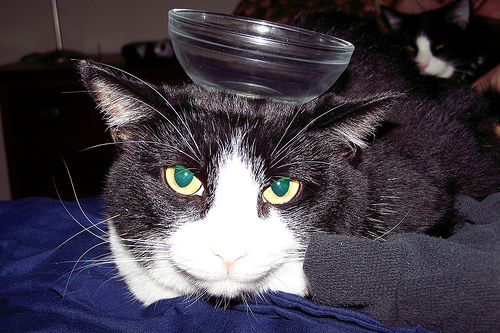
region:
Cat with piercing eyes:
[73, 60, 486, 324]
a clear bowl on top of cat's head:
[162, 8, 365, 116]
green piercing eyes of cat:
[160, 135, 312, 222]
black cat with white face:
[77, 45, 472, 312]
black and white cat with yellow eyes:
[387, 15, 492, 105]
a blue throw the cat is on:
[13, 190, 325, 331]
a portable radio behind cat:
[119, 32, 184, 83]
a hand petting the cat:
[474, 60, 499, 137]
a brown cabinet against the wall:
[13, 41, 132, 218]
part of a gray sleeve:
[314, 221, 498, 331]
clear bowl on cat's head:
[166, 8, 359, 99]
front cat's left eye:
[272, 173, 304, 207]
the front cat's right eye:
[162, 165, 207, 193]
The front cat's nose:
[207, 230, 259, 265]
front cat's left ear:
[314, 92, 409, 159]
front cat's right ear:
[83, 63, 173, 132]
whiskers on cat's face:
[50, 158, 110, 284]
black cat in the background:
[380, 3, 497, 75]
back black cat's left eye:
[432, 40, 450, 57]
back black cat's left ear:
[453, 3, 477, 33]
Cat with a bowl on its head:
[163, 20, 302, 93]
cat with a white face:
[155, 195, 287, 287]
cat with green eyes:
[154, 152, 304, 202]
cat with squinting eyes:
[386, 20, 475, 88]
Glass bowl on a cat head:
[158, 4, 327, 106]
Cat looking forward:
[52, 50, 377, 262]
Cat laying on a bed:
[111, 44, 371, 256]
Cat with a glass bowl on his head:
[132, 33, 321, 188]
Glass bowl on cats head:
[178, 32, 300, 117]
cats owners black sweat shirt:
[303, 190, 498, 331]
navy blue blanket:
[1, 184, 433, 331]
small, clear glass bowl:
[166, 7, 354, 103]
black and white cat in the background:
[378, 0, 499, 81]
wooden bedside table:
[1, 49, 193, 198]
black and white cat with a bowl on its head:
[51, 10, 491, 307]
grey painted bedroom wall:
[2, 0, 239, 202]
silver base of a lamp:
[38, 0, 93, 64]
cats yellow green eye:
[256, 173, 304, 209]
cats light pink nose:
[208, 244, 246, 274]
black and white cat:
[77, 50, 474, 307]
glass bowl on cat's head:
[160, 7, 350, 97]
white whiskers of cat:
[55, 155, 401, 283]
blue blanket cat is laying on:
[15, 197, 382, 330]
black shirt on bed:
[303, 212, 498, 329]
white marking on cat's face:
[153, 144, 298, 299]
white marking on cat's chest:
[104, 231, 311, 314]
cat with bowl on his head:
[66, 14, 498, 286]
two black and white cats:
[55, 9, 499, 310]